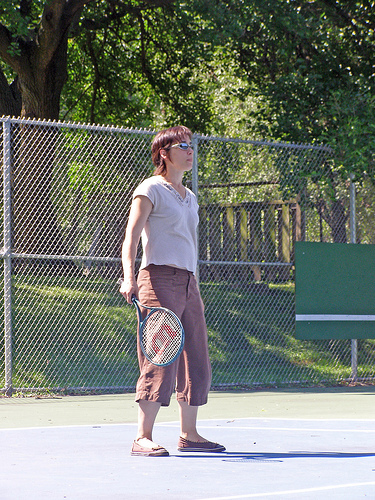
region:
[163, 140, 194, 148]
woman is wearing sunglasses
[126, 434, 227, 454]
woman is wearing a pair of brown flats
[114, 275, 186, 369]
woman is holding a tennis racket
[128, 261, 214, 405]
woman is wearing brown pants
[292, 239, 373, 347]
a green board attached to fence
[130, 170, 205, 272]
woman is wearing a tan colored shirt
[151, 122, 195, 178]
woman has short hair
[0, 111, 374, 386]
a chain linked fence in the back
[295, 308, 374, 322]
a white line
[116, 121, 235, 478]
a woman is playing tennis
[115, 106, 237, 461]
The girl is holding a tennis racket.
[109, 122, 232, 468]
The woman is wearing sunglasses.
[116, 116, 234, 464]
The woman has short hair.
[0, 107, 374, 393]
The fence is gray.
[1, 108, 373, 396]
The fence is chain link.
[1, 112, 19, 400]
The fence post is straight.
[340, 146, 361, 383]
The fence post is straight.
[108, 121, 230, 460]
The woman is wearing capris.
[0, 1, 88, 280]
The tree trunk is wide.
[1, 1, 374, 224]
The tree is leafy.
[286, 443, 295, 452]
part of a shade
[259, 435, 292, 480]
part of a shade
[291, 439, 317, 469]
part of a shade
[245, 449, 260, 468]
part of a shade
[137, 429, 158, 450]
edge of a shoe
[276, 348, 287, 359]
part of a fence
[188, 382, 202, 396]
aprt of a short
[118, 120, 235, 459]
woman in brown pants holding tennis racket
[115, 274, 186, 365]
blue and red Wilson tennis racket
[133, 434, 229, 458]
flat brown slip on sneakers on womans feet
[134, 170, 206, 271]
white shirt with v neck and cap sleeves on woman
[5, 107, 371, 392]
silver metal fence behind woman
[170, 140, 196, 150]
sunglasses on woman's face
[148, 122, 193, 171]
short reddish brown hair on female tennis player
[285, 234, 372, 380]
blank green scoreboard unused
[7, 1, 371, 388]
green park like setting behind fence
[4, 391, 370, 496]
green and white tennis court girl standing on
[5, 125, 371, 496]
A woman standing on a tennis court.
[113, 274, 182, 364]
The woman is holding a tennis racquet.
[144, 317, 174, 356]
A red letter on the white netting of the racquet.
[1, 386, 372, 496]
A green tennis court.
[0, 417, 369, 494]
white boundary lines on the tennis court.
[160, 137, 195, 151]
The woman is wearing sunglasses.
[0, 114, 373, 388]
A chain link fence behind the woman.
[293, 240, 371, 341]
A blank green and white sign.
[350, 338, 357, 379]
Metal pole supporting the sign.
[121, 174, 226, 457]
The woman is wearing matching purple cloths and shoes.